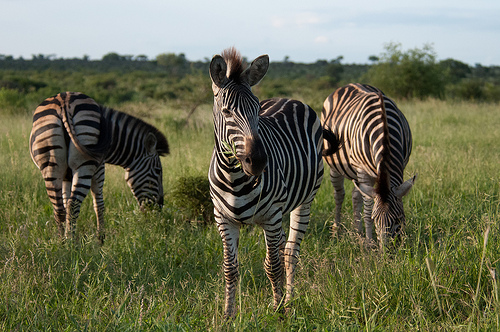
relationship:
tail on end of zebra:
[59, 96, 103, 162] [28, 90, 171, 242]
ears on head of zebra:
[208, 53, 271, 88] [203, 47, 339, 318]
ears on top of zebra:
[349, 174, 415, 196] [321, 81, 416, 253]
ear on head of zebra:
[143, 130, 157, 152] [28, 90, 171, 242]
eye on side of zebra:
[152, 166, 162, 175] [28, 90, 171, 242]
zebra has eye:
[203, 47, 339, 318] [219, 106, 233, 116]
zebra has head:
[28, 90, 171, 242] [121, 131, 166, 210]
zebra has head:
[203, 47, 339, 318] [206, 50, 274, 178]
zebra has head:
[321, 81, 416, 253] [352, 174, 417, 250]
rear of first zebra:
[28, 91, 101, 239] [28, 90, 171, 242]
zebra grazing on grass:
[28, 90, 171, 242] [0, 96, 498, 330]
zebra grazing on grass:
[321, 81, 416, 253] [0, 96, 498, 330]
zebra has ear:
[28, 90, 171, 242] [143, 130, 157, 152]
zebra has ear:
[203, 47, 339, 318] [207, 52, 230, 87]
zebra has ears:
[203, 47, 339, 318] [238, 53, 270, 88]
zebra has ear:
[321, 81, 416, 253] [393, 175, 416, 198]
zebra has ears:
[321, 81, 416, 253] [348, 179, 374, 202]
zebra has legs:
[28, 90, 171, 242] [42, 163, 107, 244]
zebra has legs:
[203, 47, 339, 318] [211, 198, 311, 312]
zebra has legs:
[321, 81, 416, 253] [329, 170, 374, 242]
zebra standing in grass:
[28, 90, 171, 242] [0, 96, 498, 330]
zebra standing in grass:
[203, 47, 339, 318] [0, 96, 498, 330]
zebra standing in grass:
[321, 81, 416, 253] [0, 96, 498, 330]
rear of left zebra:
[28, 91, 101, 239] [28, 90, 171, 242]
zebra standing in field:
[28, 90, 171, 242] [1, 42, 498, 331]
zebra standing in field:
[203, 47, 339, 318] [1, 42, 498, 331]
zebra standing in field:
[321, 81, 416, 253] [1, 42, 498, 331]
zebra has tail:
[28, 90, 171, 242] [59, 96, 103, 162]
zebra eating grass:
[28, 90, 171, 242] [0, 96, 498, 330]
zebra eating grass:
[321, 81, 416, 253] [0, 96, 498, 330]